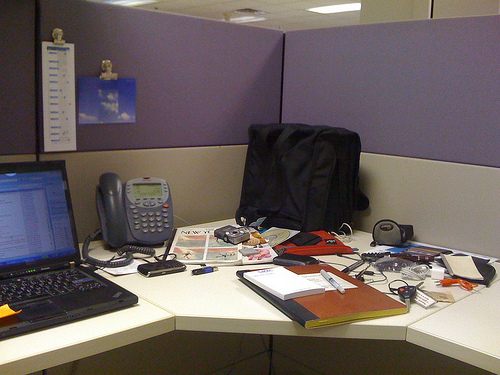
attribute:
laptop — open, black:
[2, 155, 138, 347]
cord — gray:
[79, 229, 159, 271]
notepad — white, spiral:
[239, 260, 347, 317]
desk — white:
[0, 216, 497, 373]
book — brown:
[236, 258, 405, 332]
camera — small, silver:
[213, 224, 248, 246]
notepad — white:
[240, 266, 326, 301]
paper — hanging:
[76, 61, 137, 123]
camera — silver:
[211, 213, 244, 258]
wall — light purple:
[7, 1, 499, 166]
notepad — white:
[238, 263, 330, 300]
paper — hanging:
[23, 21, 117, 186]